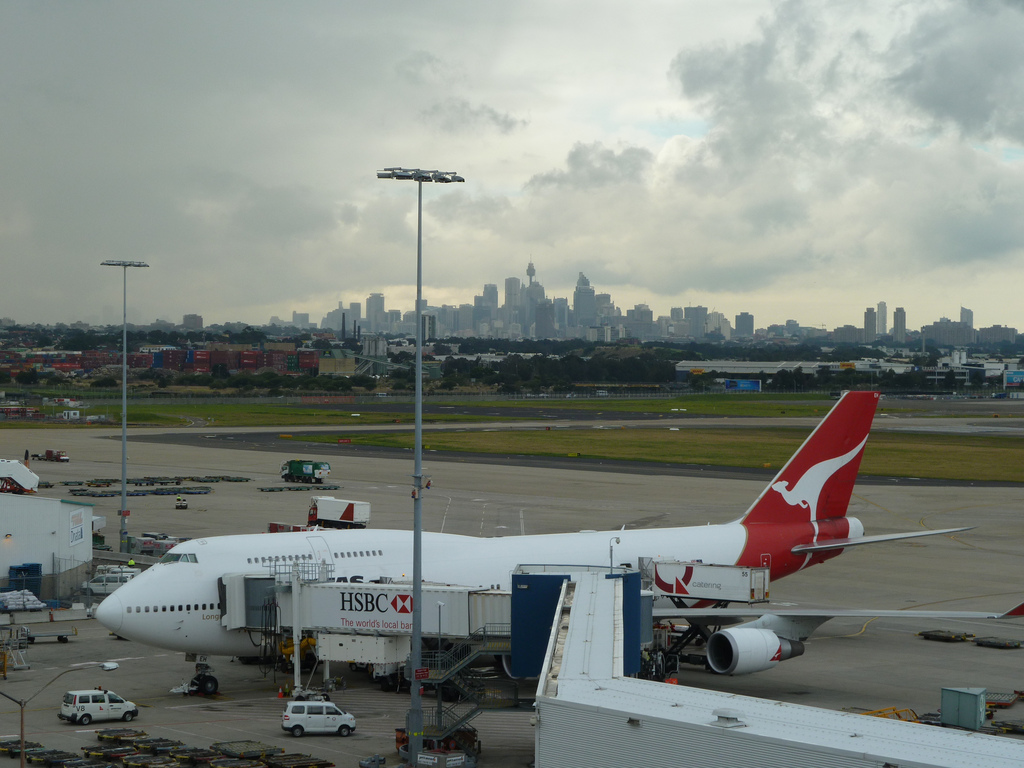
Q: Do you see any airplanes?
A: Yes, there is an airplane.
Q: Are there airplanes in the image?
A: Yes, there is an airplane.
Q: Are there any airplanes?
A: Yes, there is an airplane.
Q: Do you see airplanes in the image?
A: Yes, there is an airplane.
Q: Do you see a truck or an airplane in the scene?
A: Yes, there is an airplane.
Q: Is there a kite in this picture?
A: No, there are no kites.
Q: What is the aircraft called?
A: The aircraft is an airplane.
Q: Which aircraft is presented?
A: The aircraft is an airplane.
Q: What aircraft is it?
A: The aircraft is an airplane.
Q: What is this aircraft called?
A: This is an airplane.